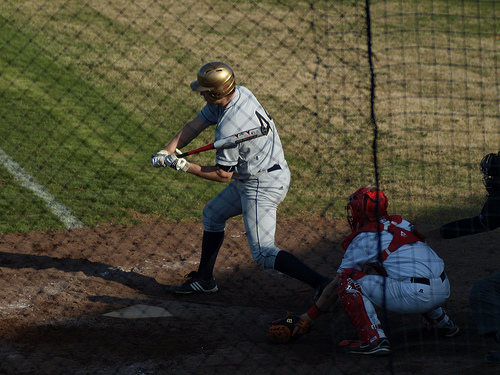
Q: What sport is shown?
A: Baseball.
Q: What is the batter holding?
A: Baseball bat.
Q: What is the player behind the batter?
A: Catcher.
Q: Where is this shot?
A: Ball park.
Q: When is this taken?
A: Daytime.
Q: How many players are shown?
A: 2.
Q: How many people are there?
A: 3.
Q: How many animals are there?
A: 0.